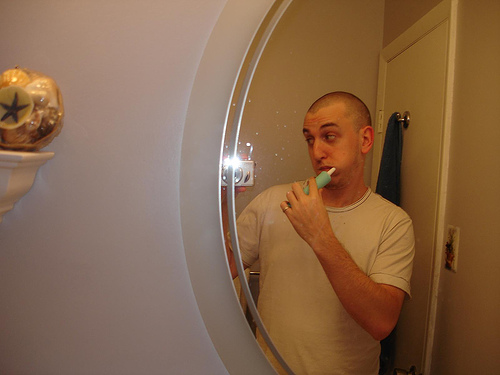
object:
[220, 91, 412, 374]
man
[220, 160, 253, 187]
camera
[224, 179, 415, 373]
shirt